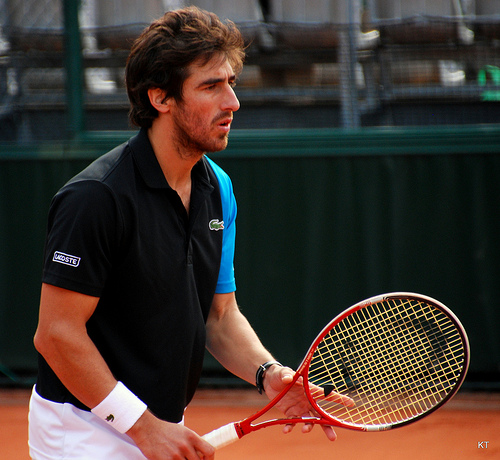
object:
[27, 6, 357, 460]
man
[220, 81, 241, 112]
nose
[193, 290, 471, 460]
racket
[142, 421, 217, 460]
hand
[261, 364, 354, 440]
hand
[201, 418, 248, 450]
handle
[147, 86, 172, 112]
ear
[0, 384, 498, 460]
ground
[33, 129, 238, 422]
shirt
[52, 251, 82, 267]
writing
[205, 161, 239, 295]
sleeve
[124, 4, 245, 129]
hair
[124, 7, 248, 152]
head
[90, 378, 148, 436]
sweatband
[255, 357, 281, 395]
wristwatch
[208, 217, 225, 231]
logo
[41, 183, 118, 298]
sleeve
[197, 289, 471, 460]
tennis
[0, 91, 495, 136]
seat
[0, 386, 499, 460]
court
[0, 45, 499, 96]
seat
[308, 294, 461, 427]
wires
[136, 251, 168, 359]
black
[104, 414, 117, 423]
logo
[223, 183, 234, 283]
blue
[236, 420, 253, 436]
red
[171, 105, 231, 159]
beard